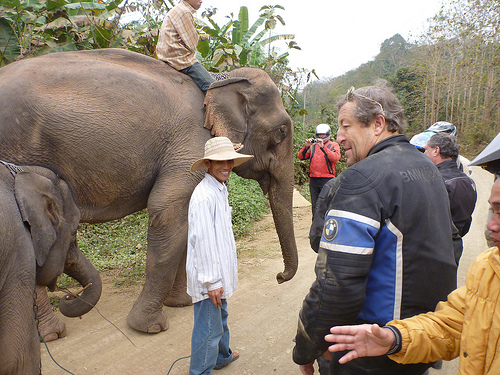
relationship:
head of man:
[337, 86, 407, 163] [292, 83, 464, 374]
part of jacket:
[316, 204, 366, 254] [285, 142, 455, 304]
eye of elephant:
[277, 122, 287, 143] [0, 40, 297, 336]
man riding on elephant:
[150, 1, 219, 89] [0, 40, 297, 336]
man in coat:
[324, 168, 498, 371] [388, 246, 498, 374]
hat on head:
[189, 140, 254, 170] [192, 146, 269, 196]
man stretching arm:
[324, 167, 500, 374] [287, 181, 362, 372]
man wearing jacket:
[292, 83, 464, 374] [304, 152, 475, 373]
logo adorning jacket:
[312, 209, 377, 259] [304, 152, 475, 373]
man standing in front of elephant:
[159, 116, 339, 372] [2, 155, 108, 373]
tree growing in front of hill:
[388, 66, 428, 128] [301, 39, 400, 111]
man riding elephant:
[153, 0, 216, 94] [0, 40, 297, 336]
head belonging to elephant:
[197, 45, 311, 212] [0, 40, 297, 336]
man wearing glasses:
[313, 67, 418, 189] [336, 80, 363, 102]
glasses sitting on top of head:
[336, 80, 363, 102] [335, 85, 406, 167]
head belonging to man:
[335, 85, 406, 167] [313, 67, 418, 189]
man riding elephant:
[153, 0, 216, 94] [20, 27, 353, 304]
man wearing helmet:
[291, 116, 342, 215] [308, 116, 332, 147]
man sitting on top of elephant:
[153, 0, 216, 94] [0, 40, 297, 336]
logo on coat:
[323, 218, 339, 241] [291, 133, 458, 374]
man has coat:
[292, 83, 464, 374] [291, 133, 458, 374]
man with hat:
[185, 134, 259, 375] [173, 112, 268, 183]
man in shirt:
[185, 134, 259, 375] [176, 172, 247, 305]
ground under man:
[395, 165, 422, 198] [185, 134, 259, 375]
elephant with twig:
[7, 12, 321, 347] [48, 275, 140, 354]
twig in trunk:
[48, 275, 140, 354] [50, 228, 107, 325]